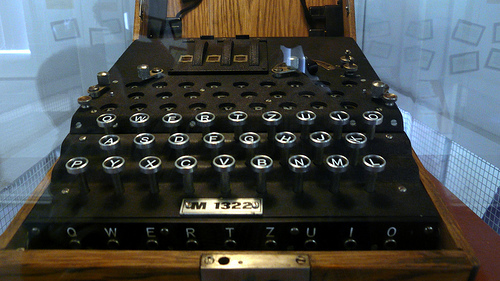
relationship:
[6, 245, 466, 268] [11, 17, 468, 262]
edge of box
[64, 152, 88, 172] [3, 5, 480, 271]
alphabet letter on a machine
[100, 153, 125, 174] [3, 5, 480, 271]
alphabet letter on a machine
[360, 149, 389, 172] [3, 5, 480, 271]
alphabet letter on a machine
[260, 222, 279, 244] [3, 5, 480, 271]
alphabet letter on a machine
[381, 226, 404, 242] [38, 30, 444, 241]
alphabet letter on a machine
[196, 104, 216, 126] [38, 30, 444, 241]
alphabet letter on a machine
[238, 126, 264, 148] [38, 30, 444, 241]
alphabet letter on a machine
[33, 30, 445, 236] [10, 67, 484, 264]
typewriter on desk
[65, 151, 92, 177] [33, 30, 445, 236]
p key on typewriter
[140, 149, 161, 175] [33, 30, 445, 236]
x key on typewriter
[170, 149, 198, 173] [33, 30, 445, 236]
c key on typewriter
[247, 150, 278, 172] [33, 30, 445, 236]
b key on typewriter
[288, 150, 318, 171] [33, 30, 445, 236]
n key on typewriter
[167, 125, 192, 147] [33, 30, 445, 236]
d key on typewriter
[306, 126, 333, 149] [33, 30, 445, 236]
j key on typewriter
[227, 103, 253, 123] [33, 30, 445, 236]
t key on typewriter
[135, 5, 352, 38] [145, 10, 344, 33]
cabinet with stripes